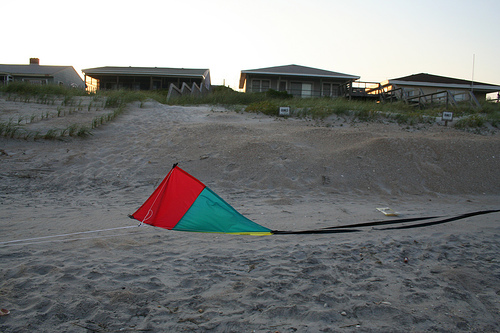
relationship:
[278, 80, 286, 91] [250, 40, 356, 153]
window on house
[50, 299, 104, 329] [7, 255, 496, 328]
footsep on ground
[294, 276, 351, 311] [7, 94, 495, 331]
footstep on ground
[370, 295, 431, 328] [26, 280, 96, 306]
footstep on footstep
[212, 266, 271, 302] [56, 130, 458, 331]
footstep on ground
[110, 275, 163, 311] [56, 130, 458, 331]
footstep on ground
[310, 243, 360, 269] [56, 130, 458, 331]
footstep on ground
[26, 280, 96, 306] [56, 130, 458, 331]
footstep on ground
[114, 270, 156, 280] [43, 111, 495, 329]
footstep on ground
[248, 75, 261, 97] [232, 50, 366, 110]
window on house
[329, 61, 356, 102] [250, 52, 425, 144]
window on house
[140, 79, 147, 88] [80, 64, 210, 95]
window on house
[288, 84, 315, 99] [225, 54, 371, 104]
window on house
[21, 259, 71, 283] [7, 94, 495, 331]
footstep in ground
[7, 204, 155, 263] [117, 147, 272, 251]
string to kite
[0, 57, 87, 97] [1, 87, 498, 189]
house on hill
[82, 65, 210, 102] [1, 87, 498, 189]
house on hill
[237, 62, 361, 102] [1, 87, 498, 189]
house on hill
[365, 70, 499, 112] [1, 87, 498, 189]
house on hill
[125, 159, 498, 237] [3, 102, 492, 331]
kite on sand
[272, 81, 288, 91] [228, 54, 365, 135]
window on house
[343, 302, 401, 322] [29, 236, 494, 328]
footstep on ground